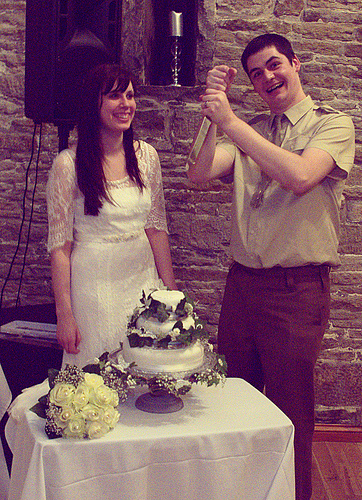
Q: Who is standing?
A: Man and woman.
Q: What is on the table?
A: Wedding cake.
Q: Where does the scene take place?
A: At a wedding reception.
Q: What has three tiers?
A: The cake.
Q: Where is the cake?
A: On table.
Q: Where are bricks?
A: On the wall.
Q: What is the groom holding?
A: Knife.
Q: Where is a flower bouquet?
A: On the table.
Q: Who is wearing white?
A: Bride.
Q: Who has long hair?
A: The woman.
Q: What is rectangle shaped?
A: Table.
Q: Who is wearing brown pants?
A: The groom.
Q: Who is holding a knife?
A: The man wearing brown.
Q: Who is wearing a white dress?
A: The woman on the left.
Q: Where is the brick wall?
A: Behind the people.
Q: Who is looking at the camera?
A: The man with the knife.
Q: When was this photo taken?
A: During a cake cutting ceremony.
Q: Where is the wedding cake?
A: On the table.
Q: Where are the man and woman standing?
A: By a wedding cake.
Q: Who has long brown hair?
A: The woman in the white dress.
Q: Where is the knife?
A: In the man's hands.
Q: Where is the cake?
A: On the table.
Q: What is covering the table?
A: A tablecloth.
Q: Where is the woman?
A: Next to the man.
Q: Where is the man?
A: Next to the woman.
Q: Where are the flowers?
A: Next to the cake.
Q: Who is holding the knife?
A: The man.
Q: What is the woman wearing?
A: A dress.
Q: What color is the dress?
A: White.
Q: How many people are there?
A: Two.